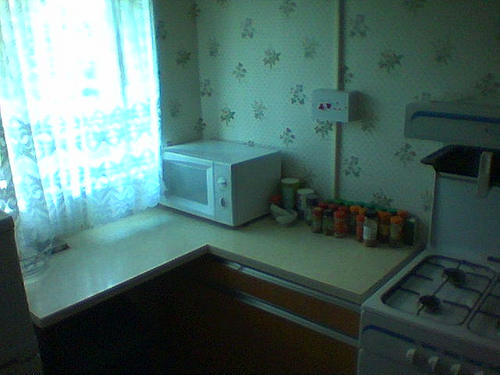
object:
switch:
[310, 88, 349, 123]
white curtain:
[0, 0, 162, 276]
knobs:
[216, 177, 228, 188]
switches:
[317, 102, 332, 110]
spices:
[281, 177, 301, 210]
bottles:
[363, 208, 379, 247]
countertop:
[24, 207, 419, 318]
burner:
[357, 248, 498, 374]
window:
[0, 0, 161, 277]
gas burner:
[443, 267, 465, 285]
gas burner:
[420, 295, 442, 314]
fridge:
[0, 210, 45, 375]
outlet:
[311, 88, 350, 123]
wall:
[191, 0, 499, 234]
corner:
[194, 243, 221, 257]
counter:
[18, 197, 425, 327]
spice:
[378, 209, 392, 243]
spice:
[390, 216, 404, 248]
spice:
[355, 214, 363, 243]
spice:
[333, 210, 347, 239]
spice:
[311, 206, 323, 233]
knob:
[427, 356, 439, 373]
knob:
[448, 363, 463, 375]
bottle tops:
[365, 210, 378, 219]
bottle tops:
[388, 207, 398, 215]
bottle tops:
[364, 201, 374, 209]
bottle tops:
[343, 200, 355, 207]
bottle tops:
[336, 198, 344, 205]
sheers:
[0, 0, 163, 277]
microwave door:
[159, 152, 215, 221]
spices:
[322, 209, 334, 236]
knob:
[405, 347, 424, 369]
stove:
[356, 97, 499, 374]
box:
[311, 89, 349, 123]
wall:
[371, 40, 461, 88]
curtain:
[0, 0, 166, 278]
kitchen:
[0, 0, 499, 375]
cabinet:
[23, 205, 421, 373]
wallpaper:
[158, 0, 499, 243]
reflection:
[82, 208, 174, 244]